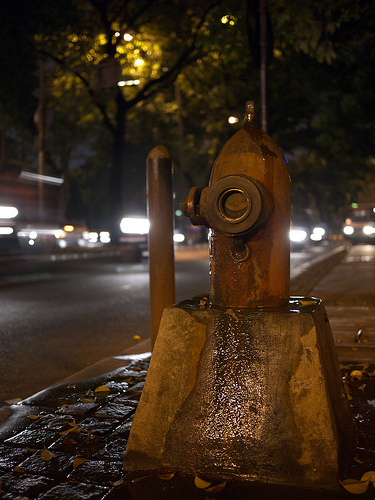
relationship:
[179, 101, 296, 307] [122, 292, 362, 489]
fire hydrant on cement block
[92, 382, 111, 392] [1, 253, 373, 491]
leaf on sidewalk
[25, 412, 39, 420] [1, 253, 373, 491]
leaf on sidewalk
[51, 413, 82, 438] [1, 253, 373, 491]
leaf on sidewalk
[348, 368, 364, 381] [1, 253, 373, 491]
leaf on sidewalk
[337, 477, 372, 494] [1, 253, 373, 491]
leaf on sidewalk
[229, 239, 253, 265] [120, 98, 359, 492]
ring hanging from fire hydrant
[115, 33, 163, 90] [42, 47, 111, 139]
lights coming through branch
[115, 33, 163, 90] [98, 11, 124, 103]
lights coming through branch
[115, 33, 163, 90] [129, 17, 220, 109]
lights coming through branch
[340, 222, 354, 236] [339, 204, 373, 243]
headlight of car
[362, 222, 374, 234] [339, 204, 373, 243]
headlight of car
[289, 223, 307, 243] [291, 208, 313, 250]
headlight of car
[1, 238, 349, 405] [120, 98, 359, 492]
street beside fire hydrant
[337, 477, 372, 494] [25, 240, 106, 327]
leaf on ground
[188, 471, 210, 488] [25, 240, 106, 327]
leaf on ground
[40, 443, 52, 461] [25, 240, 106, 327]
leaf on ground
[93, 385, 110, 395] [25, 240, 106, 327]
leaf on ground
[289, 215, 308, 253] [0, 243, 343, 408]
car driving down road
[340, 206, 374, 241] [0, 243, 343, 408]
car driving down road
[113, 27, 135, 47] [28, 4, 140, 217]
street light showing through tree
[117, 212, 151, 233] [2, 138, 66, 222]
light from business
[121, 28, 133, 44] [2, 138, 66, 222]
light from business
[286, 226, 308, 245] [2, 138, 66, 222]
light from business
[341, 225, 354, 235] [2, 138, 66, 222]
light from business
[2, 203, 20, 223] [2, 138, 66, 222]
light from business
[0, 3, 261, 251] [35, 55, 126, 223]
tree in front of sign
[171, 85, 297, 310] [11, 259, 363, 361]
fire hydrant on top of cement block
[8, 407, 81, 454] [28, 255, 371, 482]
brick in sidewalk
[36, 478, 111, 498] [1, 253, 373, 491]
brick in sidewalk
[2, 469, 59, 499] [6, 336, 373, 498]
brick in sidewalk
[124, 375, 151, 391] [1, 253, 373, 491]
brick in sidewalk